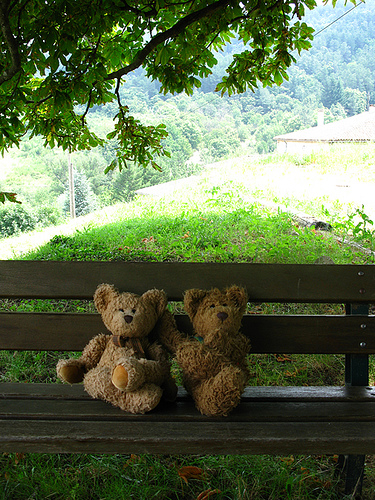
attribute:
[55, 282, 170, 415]
teddy bear — brown, sitting, stuffed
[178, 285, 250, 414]
teddy bear — sitting, brown, darker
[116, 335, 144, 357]
ribbon — brown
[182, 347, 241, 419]
legs — crossed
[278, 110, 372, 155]
building — shiny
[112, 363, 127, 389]
foot — circular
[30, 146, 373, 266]
grass — shiny, green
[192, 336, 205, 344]
bowtie — green